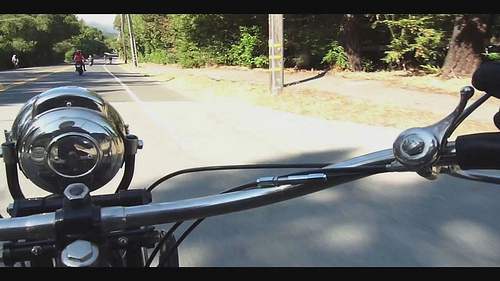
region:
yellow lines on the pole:
[259, 28, 294, 86]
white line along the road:
[101, 67, 149, 104]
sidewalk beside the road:
[175, 36, 251, 92]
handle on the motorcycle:
[434, 72, 498, 183]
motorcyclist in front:
[55, 40, 102, 82]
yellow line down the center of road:
[16, 66, 67, 81]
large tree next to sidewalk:
[419, 15, 481, 82]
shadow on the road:
[183, 143, 497, 277]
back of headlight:
[12, 90, 140, 176]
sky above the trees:
[79, 16, 132, 38]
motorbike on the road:
[64, 41, 93, 76]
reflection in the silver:
[36, 116, 108, 173]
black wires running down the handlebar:
[129, 141, 441, 266]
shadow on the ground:
[137, 138, 499, 265]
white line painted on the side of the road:
[104, 55, 186, 137]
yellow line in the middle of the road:
[0, 57, 70, 101]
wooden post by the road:
[258, 13, 294, 96]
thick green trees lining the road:
[3, 16, 125, 66]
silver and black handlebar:
[169, 41, 499, 234]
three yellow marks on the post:
[264, 35, 285, 74]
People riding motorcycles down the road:
[69, 47, 95, 74]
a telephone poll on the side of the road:
[266, 13, 286, 94]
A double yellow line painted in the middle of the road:
[0, 62, 72, 98]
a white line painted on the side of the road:
[101, 59, 218, 166]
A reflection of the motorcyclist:
[28, 116, 110, 169]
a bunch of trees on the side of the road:
[115, 10, 498, 77]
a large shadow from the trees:
[138, 145, 498, 271]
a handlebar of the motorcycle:
[161, 55, 498, 224]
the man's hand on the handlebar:
[469, 55, 499, 127]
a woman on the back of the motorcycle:
[72, 50, 86, 74]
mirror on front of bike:
[22, 108, 164, 193]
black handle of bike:
[442, 112, 498, 164]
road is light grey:
[202, 122, 324, 169]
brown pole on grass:
[267, 1, 287, 86]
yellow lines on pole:
[262, 35, 284, 88]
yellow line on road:
[0, 55, 77, 107]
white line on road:
[96, 60, 185, 159]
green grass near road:
[247, 82, 384, 124]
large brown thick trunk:
[431, 7, 493, 86]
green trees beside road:
[113, 21, 441, 70]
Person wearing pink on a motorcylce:
[70, 47, 90, 75]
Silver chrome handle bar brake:
[391, 82, 473, 179]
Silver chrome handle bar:
[0, 134, 457, 250]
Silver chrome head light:
[3, 82, 131, 192]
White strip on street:
[98, 50, 150, 102]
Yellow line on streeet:
[0, 57, 78, 105]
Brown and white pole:
[259, 11, 286, 101]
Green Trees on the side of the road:
[114, 11, 487, 78]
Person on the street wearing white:
[6, 49, 21, 71]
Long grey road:
[0, 49, 497, 269]